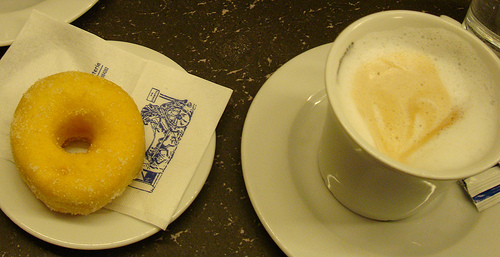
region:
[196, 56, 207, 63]
white spot on tables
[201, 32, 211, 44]
white spot on tables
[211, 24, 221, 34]
white spot on tables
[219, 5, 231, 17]
white spot on tables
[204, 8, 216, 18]
white spot on tables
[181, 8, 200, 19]
white spot on tables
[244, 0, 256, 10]
white spot on tables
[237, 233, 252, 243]
white spot on tables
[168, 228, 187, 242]
white spot on tables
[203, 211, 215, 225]
white spot on tables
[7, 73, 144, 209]
A plain donut on the napkin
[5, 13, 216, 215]
A white napkin beneath the donut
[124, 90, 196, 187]
A blue drawing on the white napkin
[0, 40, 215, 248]
A circular white plate on the table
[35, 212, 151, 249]
A white plate beneath the napkin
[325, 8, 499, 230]
A white mug on the white plate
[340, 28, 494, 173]
Coffee inside of the white mug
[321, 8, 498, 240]
A cup of coffee on the plate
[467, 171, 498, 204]
A blue and white bag by the cup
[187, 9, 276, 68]
A black table beneath the plates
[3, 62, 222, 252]
A donut on the plate.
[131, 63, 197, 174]
Napkin on the saucer.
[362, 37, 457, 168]
Expresso in the cup.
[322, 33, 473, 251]
A cup on the saucer.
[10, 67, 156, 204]
Donut sitting on top of the napkin.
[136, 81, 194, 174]
Blue design on the napkin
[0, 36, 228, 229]
A saucer sitting on the table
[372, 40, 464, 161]
Foam from the expresso.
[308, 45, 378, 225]
the cup is white.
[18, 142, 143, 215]
The donut have sugar on it.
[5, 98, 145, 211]
donut on the plate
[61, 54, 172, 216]
napkin under the donut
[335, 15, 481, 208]
liquid in the cup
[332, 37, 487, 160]
the drink is frothy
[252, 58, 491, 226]
cup on the plate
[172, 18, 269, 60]
the table is marble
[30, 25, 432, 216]
plates on the table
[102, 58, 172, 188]
pattern on the napkin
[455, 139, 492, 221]
butter on the plate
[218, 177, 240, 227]
the table is dark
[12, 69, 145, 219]
A delicious yellow doughnut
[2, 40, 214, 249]
A served doughnut in a saucer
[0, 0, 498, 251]
A readily served breakfast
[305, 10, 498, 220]
The creamy milky beverage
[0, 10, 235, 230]
A serviette on a saucer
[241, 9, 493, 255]
A beverage on a saucer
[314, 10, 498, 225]
The white drinking cup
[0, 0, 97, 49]
The top blocked saucer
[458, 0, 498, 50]
The blocked glass on the right